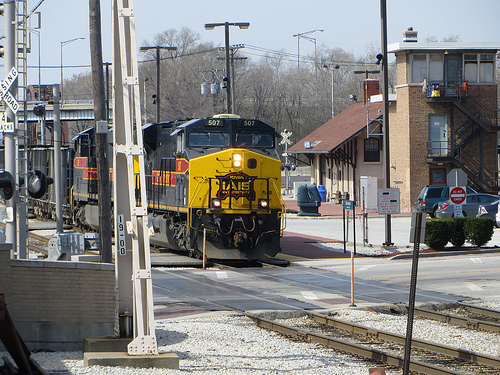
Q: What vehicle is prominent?
A: Train.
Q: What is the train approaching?
A: Street crossing.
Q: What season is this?
A: Winter.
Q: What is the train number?
A: 507.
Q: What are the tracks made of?
A: Metal.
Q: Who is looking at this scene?
A: The photographer.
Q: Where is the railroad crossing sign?
A: To the far left.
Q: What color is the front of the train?
A: Yellow.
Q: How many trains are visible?
A: One.